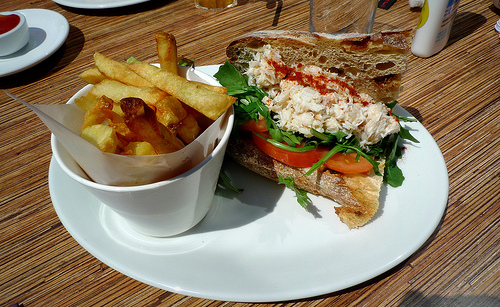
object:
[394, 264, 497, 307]
bottom right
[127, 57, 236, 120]
fries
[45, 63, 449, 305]
plate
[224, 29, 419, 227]
sandwich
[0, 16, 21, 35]
ketchup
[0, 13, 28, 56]
bowl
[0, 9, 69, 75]
plate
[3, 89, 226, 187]
paper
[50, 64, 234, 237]
bowl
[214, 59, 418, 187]
lettuce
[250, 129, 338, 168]
tomatoes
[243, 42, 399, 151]
meat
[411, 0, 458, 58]
bottle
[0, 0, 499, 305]
table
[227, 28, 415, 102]
bread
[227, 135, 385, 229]
bread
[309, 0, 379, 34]
bottle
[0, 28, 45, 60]
reflection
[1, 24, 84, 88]
reflection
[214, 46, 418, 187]
filling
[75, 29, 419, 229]
lunch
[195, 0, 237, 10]
glass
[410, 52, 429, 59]
edge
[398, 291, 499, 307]
shadow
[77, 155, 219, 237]
front